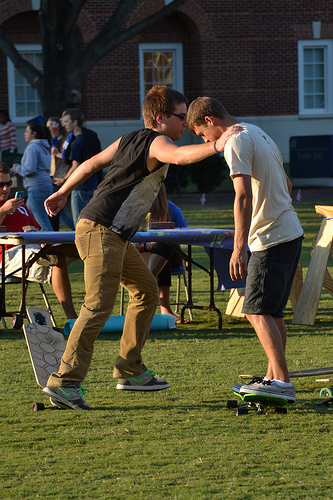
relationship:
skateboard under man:
[246, 396, 289, 412] [182, 84, 298, 394]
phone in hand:
[219, 277, 241, 289] [216, 253, 247, 282]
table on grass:
[168, 233, 197, 246] [188, 356, 223, 372]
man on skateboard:
[182, 84, 298, 394] [246, 396, 289, 412]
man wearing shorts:
[182, 84, 298, 394] [236, 258, 300, 309]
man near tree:
[182, 84, 298, 394] [38, 8, 124, 96]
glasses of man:
[167, 114, 190, 121] [182, 84, 298, 394]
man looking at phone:
[182, 84, 298, 394] [219, 277, 241, 289]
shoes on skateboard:
[47, 372, 180, 416] [246, 396, 289, 412]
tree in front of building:
[38, 8, 124, 96] [230, 6, 279, 115]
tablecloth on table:
[14, 232, 50, 256] [168, 233, 197, 246]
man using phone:
[182, 84, 298, 394] [219, 277, 241, 289]